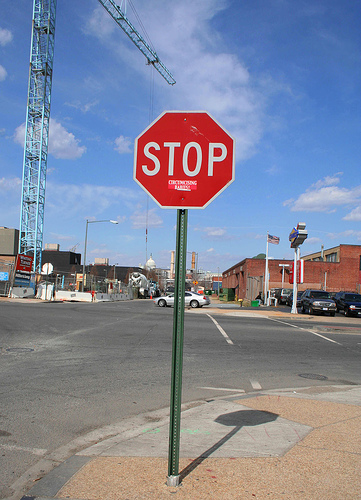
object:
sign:
[133, 110, 236, 210]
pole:
[166, 210, 189, 487]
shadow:
[180, 409, 279, 484]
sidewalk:
[12, 384, 359, 500]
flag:
[266, 234, 284, 247]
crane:
[9, 2, 178, 301]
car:
[151, 288, 210, 306]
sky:
[1, 2, 361, 273]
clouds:
[2, 175, 168, 232]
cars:
[263, 287, 360, 317]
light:
[81, 218, 120, 291]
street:
[2, 294, 360, 499]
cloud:
[14, 117, 85, 162]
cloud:
[279, 176, 361, 223]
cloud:
[111, 1, 295, 172]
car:
[331, 291, 359, 320]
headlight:
[349, 304, 354, 309]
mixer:
[127, 272, 157, 298]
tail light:
[203, 296, 206, 301]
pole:
[264, 238, 270, 306]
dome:
[139, 254, 157, 271]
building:
[0, 226, 360, 310]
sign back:
[40, 262, 55, 276]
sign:
[15, 254, 36, 273]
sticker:
[168, 179, 198, 193]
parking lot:
[260, 303, 360, 319]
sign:
[288, 223, 308, 251]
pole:
[291, 249, 300, 314]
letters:
[141, 141, 225, 178]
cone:
[148, 292, 156, 302]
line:
[203, 311, 233, 346]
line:
[265, 315, 342, 344]